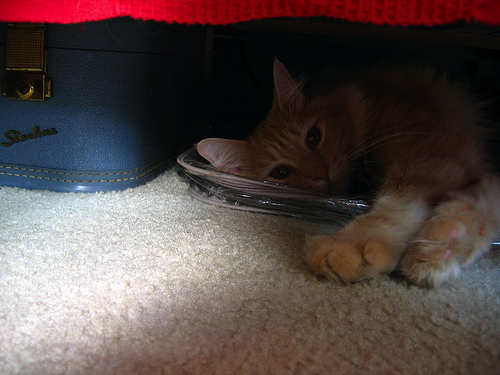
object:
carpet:
[0, 171, 498, 367]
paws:
[304, 227, 397, 285]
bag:
[173, 141, 371, 222]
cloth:
[1, 0, 484, 28]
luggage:
[2, 19, 211, 193]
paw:
[397, 199, 483, 289]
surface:
[2, 163, 484, 373]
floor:
[2, 165, 499, 374]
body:
[383, 58, 488, 141]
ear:
[193, 136, 258, 177]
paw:
[297, 209, 413, 285]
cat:
[193, 55, 496, 288]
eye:
[262, 156, 294, 181]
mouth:
[319, 168, 351, 193]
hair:
[375, 73, 479, 145]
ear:
[268, 57, 305, 111]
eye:
[300, 119, 325, 154]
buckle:
[3, 71, 42, 100]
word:
[2, 123, 58, 147]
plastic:
[170, 153, 371, 223]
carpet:
[4, 213, 289, 371]